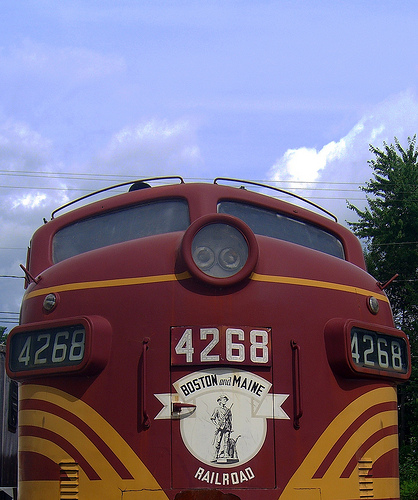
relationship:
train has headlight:
[7, 166, 412, 497] [177, 211, 260, 293]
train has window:
[7, 166, 412, 497] [47, 191, 192, 264]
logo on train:
[147, 367, 293, 487] [7, 166, 412, 497]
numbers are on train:
[171, 327, 270, 367] [7, 166, 412, 497]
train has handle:
[7, 166, 412, 497] [375, 269, 399, 298]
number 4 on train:
[14, 334, 33, 370] [7, 166, 412, 497]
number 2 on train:
[34, 332, 53, 366] [7, 166, 412, 497]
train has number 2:
[7, 166, 412, 497] [34, 332, 53, 366]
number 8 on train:
[65, 326, 88, 367] [7, 166, 412, 497]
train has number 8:
[7, 166, 412, 497] [65, 326, 88, 367]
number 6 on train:
[51, 328, 69, 366] [7, 166, 412, 497]